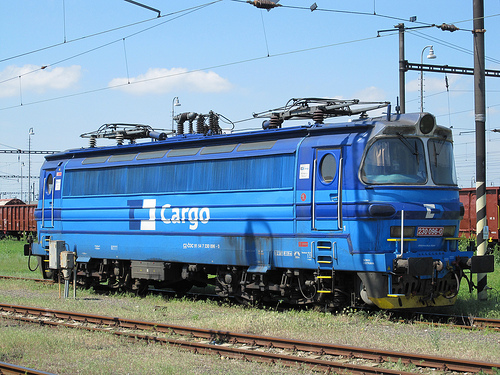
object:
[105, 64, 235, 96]
cloud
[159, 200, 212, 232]
"cargo"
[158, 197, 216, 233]
cargo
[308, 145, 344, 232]
door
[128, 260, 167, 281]
engine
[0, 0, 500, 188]
sky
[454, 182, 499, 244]
car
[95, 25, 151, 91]
wires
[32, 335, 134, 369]
grassy landscape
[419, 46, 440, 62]
lamp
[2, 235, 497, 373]
grass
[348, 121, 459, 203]
windshield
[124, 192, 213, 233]
cargo logo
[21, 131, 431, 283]
side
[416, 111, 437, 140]
headlight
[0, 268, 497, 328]
railroad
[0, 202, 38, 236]
car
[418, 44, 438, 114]
lightpost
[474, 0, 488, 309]
poles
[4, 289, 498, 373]
tracks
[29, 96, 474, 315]
train